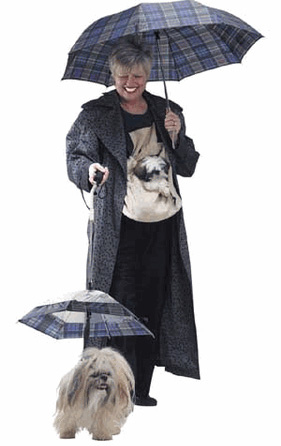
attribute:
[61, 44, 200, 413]
woman — grinning, existing, smiling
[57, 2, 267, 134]
umbrella — gray, blue, existing, open, patterned, large, purple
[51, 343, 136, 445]
dog — shaggy, existing, white, brown, long haired, small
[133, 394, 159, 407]
shoe — black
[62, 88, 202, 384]
coat — blue, gray, black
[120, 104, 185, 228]
shit — black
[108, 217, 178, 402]
trousers — black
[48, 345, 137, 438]
hair — long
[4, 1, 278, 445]
background — white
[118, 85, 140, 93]
teeth — white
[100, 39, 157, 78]
hair — blonde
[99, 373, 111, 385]
nose — black